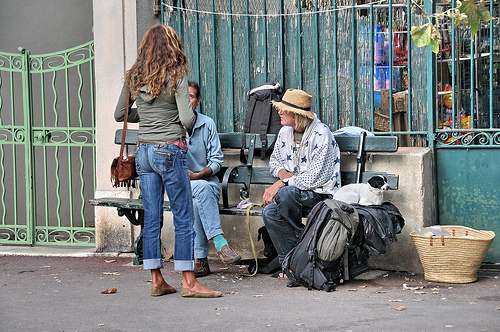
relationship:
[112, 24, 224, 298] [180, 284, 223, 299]
woman wearing flats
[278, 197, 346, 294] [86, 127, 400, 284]
pack by bench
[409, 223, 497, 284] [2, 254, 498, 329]
basket on sidewalk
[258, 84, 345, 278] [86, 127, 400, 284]
person on bench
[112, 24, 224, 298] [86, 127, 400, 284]
woman by bench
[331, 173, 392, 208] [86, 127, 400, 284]
dog on bench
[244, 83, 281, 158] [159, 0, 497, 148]
backpack on railing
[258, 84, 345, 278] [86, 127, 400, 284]
person sitting on bench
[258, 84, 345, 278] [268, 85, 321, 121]
person has on a hat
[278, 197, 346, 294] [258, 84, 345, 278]
pack next to person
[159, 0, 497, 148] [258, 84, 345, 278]
railing behind person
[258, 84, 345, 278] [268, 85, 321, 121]
person has a hat